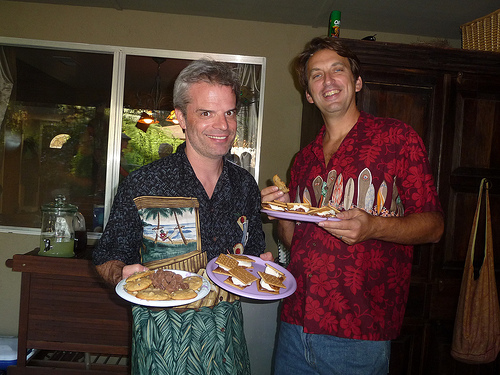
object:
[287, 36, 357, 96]
hair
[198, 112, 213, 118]
eyes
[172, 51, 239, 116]
silver hair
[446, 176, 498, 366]
bag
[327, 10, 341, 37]
spray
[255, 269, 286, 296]
smores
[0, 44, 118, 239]
window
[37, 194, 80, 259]
container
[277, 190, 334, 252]
plate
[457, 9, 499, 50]
basket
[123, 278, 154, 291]
cookies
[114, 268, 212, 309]
white plate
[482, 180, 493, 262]
straps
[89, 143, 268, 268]
shirt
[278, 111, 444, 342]
red shirt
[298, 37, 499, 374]
cupboard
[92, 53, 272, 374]
guy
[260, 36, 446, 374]
guy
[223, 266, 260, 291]
food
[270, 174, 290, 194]
food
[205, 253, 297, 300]
plate